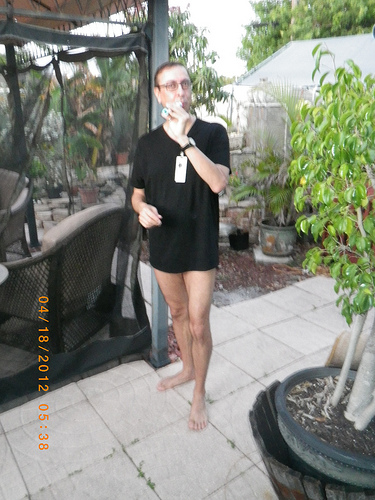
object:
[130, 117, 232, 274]
shirt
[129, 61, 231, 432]
man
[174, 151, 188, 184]
badge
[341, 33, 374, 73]
ground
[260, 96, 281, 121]
ground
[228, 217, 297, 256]
pot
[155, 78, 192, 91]
glasses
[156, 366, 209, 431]
feet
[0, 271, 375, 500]
cement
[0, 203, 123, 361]
chair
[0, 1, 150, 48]
awning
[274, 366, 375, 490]
pot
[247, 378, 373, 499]
barrel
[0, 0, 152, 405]
bug netting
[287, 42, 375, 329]
green leaves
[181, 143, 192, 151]
band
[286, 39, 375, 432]
tree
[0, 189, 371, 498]
ground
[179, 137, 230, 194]
arm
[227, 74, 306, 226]
plant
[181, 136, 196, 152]
watch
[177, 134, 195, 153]
wrist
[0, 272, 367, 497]
tiles